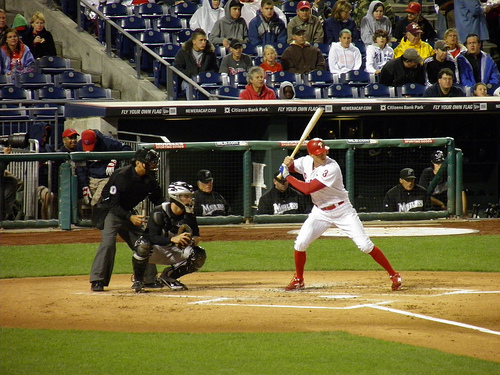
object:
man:
[273, 137, 403, 292]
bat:
[279, 102, 323, 183]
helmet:
[305, 137, 330, 155]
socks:
[292, 246, 308, 277]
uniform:
[292, 159, 370, 249]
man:
[394, 22, 435, 62]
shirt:
[393, 38, 434, 60]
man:
[130, 178, 206, 292]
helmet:
[167, 179, 195, 205]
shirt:
[292, 154, 351, 204]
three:
[322, 166, 331, 179]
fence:
[1, 136, 456, 217]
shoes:
[282, 276, 307, 293]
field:
[0, 213, 499, 373]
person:
[171, 26, 216, 100]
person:
[217, 37, 255, 74]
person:
[391, 3, 438, 48]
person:
[453, 34, 499, 97]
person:
[286, 1, 324, 44]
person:
[328, 28, 361, 78]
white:
[329, 43, 363, 74]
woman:
[241, 66, 273, 99]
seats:
[0, 0, 500, 109]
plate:
[317, 287, 351, 302]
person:
[365, 32, 393, 80]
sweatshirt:
[365, 41, 396, 77]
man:
[425, 67, 468, 98]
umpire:
[89, 141, 163, 293]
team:
[196, 162, 449, 211]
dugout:
[83, 97, 500, 218]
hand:
[277, 155, 293, 172]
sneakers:
[386, 266, 402, 292]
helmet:
[130, 147, 162, 180]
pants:
[93, 204, 150, 287]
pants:
[291, 199, 375, 257]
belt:
[310, 200, 349, 210]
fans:
[0, 1, 492, 103]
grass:
[0, 325, 499, 373]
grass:
[0, 233, 498, 276]